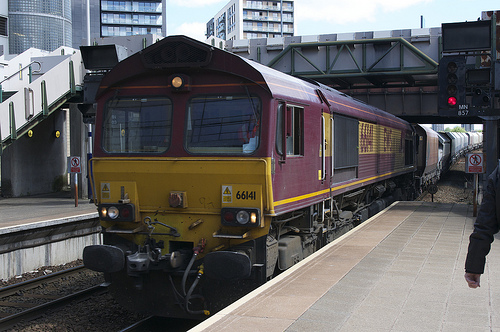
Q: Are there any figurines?
A: No, there are no figurines.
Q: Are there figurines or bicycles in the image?
A: No, there are no figurines or bicycles.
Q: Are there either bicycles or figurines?
A: No, there are no figurines or bicycles.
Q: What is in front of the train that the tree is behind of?
A: The wires are in front of the train.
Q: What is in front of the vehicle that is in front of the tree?
A: The wires are in front of the train.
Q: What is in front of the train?
A: The wires are in front of the train.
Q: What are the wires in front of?
A: The wires are in front of the train.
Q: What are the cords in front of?
A: The wires are in front of the train.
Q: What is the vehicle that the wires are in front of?
A: The vehicle is a train.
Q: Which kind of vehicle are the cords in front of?
A: The wires are in front of the train.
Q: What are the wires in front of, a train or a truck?
A: The wires are in front of a train.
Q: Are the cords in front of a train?
A: Yes, the cords are in front of a train.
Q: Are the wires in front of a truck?
A: No, the wires are in front of a train.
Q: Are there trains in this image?
A: Yes, there is a train.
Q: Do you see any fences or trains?
A: Yes, there is a train.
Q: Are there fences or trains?
A: Yes, there is a train.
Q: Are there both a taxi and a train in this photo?
A: No, there is a train but no taxis.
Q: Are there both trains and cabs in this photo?
A: No, there is a train but no taxis.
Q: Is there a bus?
A: No, there are no buses.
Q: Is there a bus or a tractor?
A: No, there are no buses or tractors.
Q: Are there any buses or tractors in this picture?
A: No, there are no buses or tractors.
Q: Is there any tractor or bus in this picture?
A: No, there are no buses or tractors.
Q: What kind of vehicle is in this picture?
A: The vehicle is a train.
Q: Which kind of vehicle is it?
A: The vehicle is a train.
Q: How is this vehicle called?
A: This is a train.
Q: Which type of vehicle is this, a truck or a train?
A: This is a train.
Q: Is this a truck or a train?
A: This is a train.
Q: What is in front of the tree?
A: The train is in front of the tree.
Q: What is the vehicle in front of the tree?
A: The vehicle is a train.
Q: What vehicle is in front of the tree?
A: The vehicle is a train.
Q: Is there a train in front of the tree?
A: Yes, there is a train in front of the tree.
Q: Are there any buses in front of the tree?
A: No, there is a train in front of the tree.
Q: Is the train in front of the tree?
A: Yes, the train is in front of the tree.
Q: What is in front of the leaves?
A: The train is in front of the leaves.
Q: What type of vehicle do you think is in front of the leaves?
A: The vehicle is a train.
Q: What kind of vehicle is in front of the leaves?
A: The vehicle is a train.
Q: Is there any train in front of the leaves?
A: Yes, there is a train in front of the leaves.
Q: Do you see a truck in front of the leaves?
A: No, there is a train in front of the leaves.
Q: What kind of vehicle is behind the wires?
A: The vehicle is a train.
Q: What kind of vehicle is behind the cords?
A: The vehicle is a train.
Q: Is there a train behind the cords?
A: Yes, there is a train behind the cords.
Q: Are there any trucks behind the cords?
A: No, there is a train behind the cords.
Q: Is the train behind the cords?
A: Yes, the train is behind the cords.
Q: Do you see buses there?
A: No, there are no buses.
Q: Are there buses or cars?
A: No, there are no buses or cars.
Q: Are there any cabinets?
A: No, there are no cabinets.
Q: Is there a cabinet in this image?
A: No, there are no cabinets.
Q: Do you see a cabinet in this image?
A: No, there are no cabinets.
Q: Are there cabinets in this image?
A: No, there are no cabinets.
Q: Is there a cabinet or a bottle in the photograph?
A: No, there are no cabinets or bottles.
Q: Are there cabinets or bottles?
A: No, there are no cabinets or bottles.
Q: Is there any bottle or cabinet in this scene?
A: No, there are no cabinets or bottles.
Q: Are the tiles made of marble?
A: No, the tiles are made of stone.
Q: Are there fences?
A: No, there are no fences.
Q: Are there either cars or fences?
A: No, there are no fences or cars.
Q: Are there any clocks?
A: No, there are no clocks.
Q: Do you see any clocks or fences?
A: No, there are no clocks or fences.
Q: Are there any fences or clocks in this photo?
A: No, there are no clocks or fences.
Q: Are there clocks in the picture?
A: No, there are no clocks.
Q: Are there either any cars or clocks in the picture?
A: No, there are no clocks or cars.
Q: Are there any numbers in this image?
A: Yes, there are numbers.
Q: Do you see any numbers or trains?
A: Yes, there are numbers.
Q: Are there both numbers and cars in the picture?
A: No, there are numbers but no cars.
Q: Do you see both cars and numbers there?
A: No, there are numbers but no cars.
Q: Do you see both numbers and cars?
A: No, there are numbers but no cars.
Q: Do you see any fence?
A: No, there are no fences.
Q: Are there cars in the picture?
A: No, there are no cars.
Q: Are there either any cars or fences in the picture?
A: No, there are no cars or fences.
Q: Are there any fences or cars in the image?
A: No, there are no cars or fences.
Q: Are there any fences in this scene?
A: No, there are no fences.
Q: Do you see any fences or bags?
A: No, there are no fences or bags.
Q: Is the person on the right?
A: Yes, the person is on the right of the image.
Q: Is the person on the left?
A: No, the person is on the right of the image.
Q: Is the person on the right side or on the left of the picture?
A: The person is on the right of the image.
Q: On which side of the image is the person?
A: The person is on the right of the image.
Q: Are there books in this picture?
A: No, there are no books.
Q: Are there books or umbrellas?
A: No, there are no books or umbrellas.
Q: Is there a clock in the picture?
A: No, there are no clocks.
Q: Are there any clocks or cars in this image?
A: No, there are no clocks or cars.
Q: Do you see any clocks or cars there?
A: No, there are no clocks or cars.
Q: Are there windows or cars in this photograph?
A: Yes, there is a window.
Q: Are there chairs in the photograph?
A: No, there are no chairs.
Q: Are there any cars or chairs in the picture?
A: No, there are no chairs or cars.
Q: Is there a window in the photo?
A: Yes, there is a window.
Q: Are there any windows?
A: Yes, there is a window.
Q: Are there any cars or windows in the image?
A: Yes, there is a window.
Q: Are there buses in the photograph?
A: No, there are no buses.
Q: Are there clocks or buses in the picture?
A: No, there are no buses or clocks.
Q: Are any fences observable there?
A: No, there are no fences.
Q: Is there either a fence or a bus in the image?
A: No, there are no fences or buses.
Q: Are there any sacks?
A: No, there are no sacks.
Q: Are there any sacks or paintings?
A: No, there are no sacks or paintings.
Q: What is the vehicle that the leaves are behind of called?
A: The vehicle is a train.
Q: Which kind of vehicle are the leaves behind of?
A: The leaves are behind the train.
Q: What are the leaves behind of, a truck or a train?
A: The leaves are behind a train.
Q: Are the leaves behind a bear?
A: No, the leaves are behind the train.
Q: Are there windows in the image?
A: Yes, there are windows.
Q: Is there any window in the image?
A: Yes, there are windows.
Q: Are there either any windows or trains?
A: Yes, there are windows.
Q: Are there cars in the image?
A: No, there are no cars.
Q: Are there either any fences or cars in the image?
A: No, there are no cars or fences.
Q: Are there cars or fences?
A: No, there are no fences or cars.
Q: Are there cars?
A: No, there are no cars.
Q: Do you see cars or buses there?
A: No, there are no cars or buses.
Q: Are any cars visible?
A: No, there are no cars.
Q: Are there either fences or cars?
A: No, there are no cars or fences.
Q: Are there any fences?
A: No, there are no fences.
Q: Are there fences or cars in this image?
A: No, there are no fences or cars.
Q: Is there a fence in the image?
A: No, there are no fences.